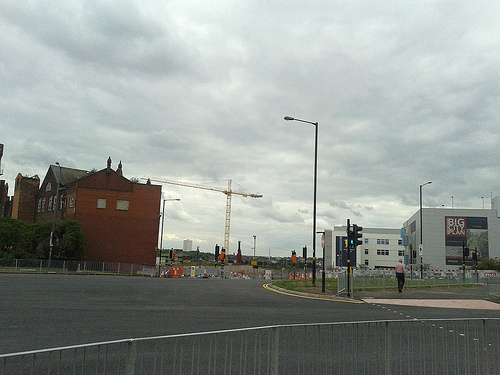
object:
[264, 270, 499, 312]
street corner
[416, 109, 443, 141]
ground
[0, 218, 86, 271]
bushes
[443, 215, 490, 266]
advertisement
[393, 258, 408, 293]
man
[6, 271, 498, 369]
sidewalk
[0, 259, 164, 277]
fence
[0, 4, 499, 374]
background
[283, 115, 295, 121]
light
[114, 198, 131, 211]
window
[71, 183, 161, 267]
wall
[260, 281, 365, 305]
line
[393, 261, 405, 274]
shirt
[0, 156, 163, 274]
building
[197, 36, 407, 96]
clouds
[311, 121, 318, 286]
light pole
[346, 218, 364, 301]
traffic light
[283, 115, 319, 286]
street light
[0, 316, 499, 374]
fence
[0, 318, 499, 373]
railing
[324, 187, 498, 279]
building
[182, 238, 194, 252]
building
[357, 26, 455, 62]
sky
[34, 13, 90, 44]
grey clouds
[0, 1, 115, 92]
sky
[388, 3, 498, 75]
clouds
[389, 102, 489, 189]
clouds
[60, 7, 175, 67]
clouds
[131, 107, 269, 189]
clouds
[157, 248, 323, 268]
construction site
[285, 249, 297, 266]
sign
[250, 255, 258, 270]
sign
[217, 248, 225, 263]
sign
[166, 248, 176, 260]
sign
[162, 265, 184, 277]
sign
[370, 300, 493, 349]
line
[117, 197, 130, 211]
squares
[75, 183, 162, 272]
side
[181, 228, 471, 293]
site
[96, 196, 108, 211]
blinds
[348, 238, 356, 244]
light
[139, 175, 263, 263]
construction crane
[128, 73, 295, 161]
sky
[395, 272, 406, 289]
chinos